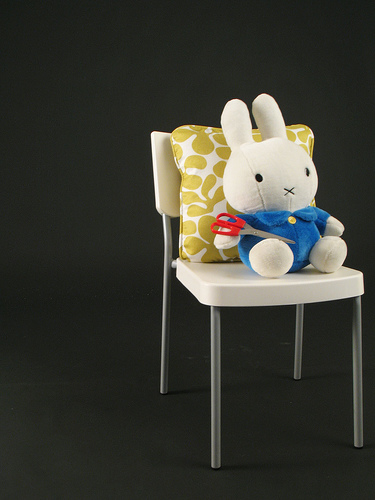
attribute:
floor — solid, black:
[0, 319, 375, 500]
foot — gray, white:
[244, 238, 301, 281]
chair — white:
[151, 132, 375, 472]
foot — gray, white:
[314, 235, 352, 275]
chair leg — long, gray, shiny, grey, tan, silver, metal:
[161, 267, 173, 396]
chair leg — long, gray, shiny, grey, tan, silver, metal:
[206, 307, 231, 472]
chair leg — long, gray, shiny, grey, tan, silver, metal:
[291, 308, 308, 384]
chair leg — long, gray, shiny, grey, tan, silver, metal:
[351, 296, 367, 449]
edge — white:
[208, 274, 369, 290]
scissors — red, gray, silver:
[210, 213, 302, 247]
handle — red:
[212, 211, 250, 240]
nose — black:
[282, 185, 299, 198]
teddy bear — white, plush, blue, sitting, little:
[212, 94, 349, 279]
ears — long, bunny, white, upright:
[219, 94, 296, 149]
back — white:
[152, 130, 195, 215]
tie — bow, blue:
[257, 207, 321, 225]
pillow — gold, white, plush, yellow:
[178, 125, 319, 260]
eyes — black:
[252, 170, 266, 185]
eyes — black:
[304, 166, 313, 180]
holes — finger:
[221, 215, 235, 223]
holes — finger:
[215, 224, 233, 233]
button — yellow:
[287, 215, 299, 225]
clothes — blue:
[231, 207, 329, 273]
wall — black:
[1, 1, 375, 296]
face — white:
[225, 147, 320, 213]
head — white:
[216, 97, 326, 213]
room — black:
[1, 3, 374, 495]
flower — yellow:
[182, 129, 216, 156]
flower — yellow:
[186, 180, 222, 216]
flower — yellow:
[191, 217, 229, 264]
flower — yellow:
[288, 125, 315, 152]